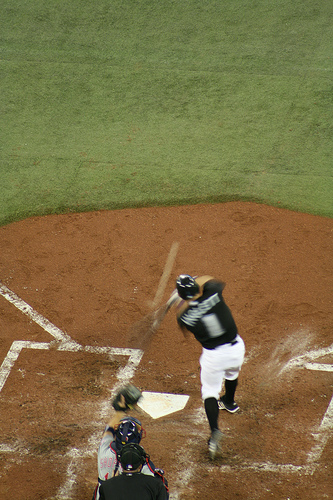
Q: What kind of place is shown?
A: It is a field.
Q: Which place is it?
A: It is a field.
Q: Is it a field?
A: Yes, it is a field.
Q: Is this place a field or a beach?
A: It is a field.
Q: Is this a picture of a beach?
A: No, the picture is showing a field.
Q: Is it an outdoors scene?
A: Yes, it is outdoors.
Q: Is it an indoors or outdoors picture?
A: It is outdoors.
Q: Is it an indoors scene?
A: No, it is outdoors.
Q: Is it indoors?
A: No, it is outdoors.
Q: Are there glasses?
A: No, there are no glasses.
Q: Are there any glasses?
A: No, there are no glasses.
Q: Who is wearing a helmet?
A: The man is wearing a helmet.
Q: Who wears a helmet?
A: The man wears a helmet.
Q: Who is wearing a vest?
A: The man is wearing a vest.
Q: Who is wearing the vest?
A: The man is wearing a vest.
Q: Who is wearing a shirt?
A: The man is wearing a shirt.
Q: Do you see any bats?
A: Yes, there is a bat.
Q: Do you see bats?
A: Yes, there is a bat.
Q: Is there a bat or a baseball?
A: Yes, there is a bat.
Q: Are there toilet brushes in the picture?
A: No, there are no toilet brushes.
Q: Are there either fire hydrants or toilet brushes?
A: No, there are no toilet brushes or fire hydrants.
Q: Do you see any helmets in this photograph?
A: Yes, there is a helmet.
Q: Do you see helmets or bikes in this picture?
A: Yes, there is a helmet.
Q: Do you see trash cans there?
A: No, there are no trash cans.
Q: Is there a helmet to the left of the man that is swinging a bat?
A: Yes, there is a helmet to the left of the man.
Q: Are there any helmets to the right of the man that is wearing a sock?
A: No, the helmet is to the left of the man.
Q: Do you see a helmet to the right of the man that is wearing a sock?
A: No, the helmet is to the left of the man.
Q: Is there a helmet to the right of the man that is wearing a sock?
A: No, the helmet is to the left of the man.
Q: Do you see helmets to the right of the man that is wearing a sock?
A: No, the helmet is to the left of the man.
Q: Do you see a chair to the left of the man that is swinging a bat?
A: No, there is a helmet to the left of the man.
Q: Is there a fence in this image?
A: No, there are no fences.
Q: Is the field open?
A: Yes, the field is open.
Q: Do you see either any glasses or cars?
A: No, there are no glasses or cars.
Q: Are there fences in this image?
A: No, there are no fences.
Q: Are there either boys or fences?
A: No, there are no fences or boys.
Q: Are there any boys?
A: No, there are no boys.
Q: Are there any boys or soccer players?
A: No, there are no boys or soccer players.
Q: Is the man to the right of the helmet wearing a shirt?
A: Yes, the man is wearing a shirt.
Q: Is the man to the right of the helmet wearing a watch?
A: No, the man is wearing a shirt.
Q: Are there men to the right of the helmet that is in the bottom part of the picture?
A: Yes, there is a man to the right of the helmet.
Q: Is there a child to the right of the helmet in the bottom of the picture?
A: No, there is a man to the right of the helmet.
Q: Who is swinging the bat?
A: The man is swinging the bat.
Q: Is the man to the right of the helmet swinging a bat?
A: Yes, the man is swinging a bat.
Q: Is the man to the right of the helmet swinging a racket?
A: No, the man is swinging a bat.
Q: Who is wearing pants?
A: The man is wearing pants.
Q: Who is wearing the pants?
A: The man is wearing pants.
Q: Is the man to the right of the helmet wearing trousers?
A: Yes, the man is wearing trousers.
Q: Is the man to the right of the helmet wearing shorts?
A: No, the man is wearing trousers.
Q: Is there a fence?
A: No, there are no fences.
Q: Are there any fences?
A: No, there are no fences.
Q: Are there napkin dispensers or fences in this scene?
A: No, there are no fences or napkin dispensers.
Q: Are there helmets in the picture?
A: Yes, there is a helmet.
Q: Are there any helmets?
A: Yes, there is a helmet.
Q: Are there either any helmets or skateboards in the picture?
A: Yes, there is a helmet.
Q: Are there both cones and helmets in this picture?
A: No, there is a helmet but no cones.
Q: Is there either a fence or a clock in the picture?
A: No, there are no fences or clocks.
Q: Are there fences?
A: No, there are no fences.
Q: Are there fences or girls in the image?
A: No, there are no fences or girls.